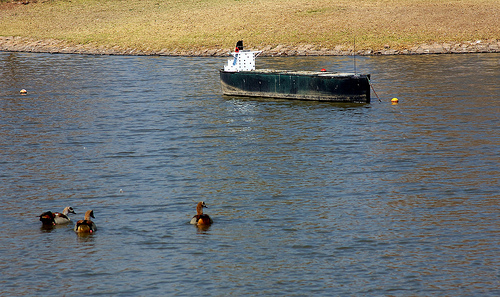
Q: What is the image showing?
A: It is showing a lake.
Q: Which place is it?
A: It is a lake.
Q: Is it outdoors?
A: Yes, it is outdoors.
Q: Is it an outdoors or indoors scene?
A: It is outdoors.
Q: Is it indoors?
A: No, it is outdoors.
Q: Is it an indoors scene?
A: No, it is outdoors.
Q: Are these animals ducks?
A: Yes, all the animals are ducks.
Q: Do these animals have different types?
A: No, all the animals are ducks.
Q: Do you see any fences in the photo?
A: No, there are no fences.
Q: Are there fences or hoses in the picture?
A: No, there are no fences or hoses.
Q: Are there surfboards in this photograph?
A: No, there are no surfboards.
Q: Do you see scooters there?
A: No, there are no scooters.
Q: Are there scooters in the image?
A: No, there are no scooters.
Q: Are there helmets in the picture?
A: No, there are no helmets.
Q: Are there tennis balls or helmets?
A: No, there are no helmets or tennis balls.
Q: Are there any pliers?
A: No, there are no pliers.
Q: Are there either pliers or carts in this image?
A: No, there are no pliers or carts.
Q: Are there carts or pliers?
A: No, there are no pliers or carts.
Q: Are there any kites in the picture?
A: No, there are no kites.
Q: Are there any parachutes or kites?
A: No, there are no kites or parachutes.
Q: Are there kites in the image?
A: No, there are no kites.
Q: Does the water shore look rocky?
A: Yes, the shore is rocky.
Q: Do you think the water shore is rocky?
A: Yes, the shore is rocky.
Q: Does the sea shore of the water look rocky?
A: Yes, the shore is rocky.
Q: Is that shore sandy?
A: No, the shore is rocky.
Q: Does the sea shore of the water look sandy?
A: No, the shore is rocky.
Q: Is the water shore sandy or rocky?
A: The shore is rocky.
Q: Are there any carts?
A: No, there are no carts.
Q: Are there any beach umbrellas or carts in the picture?
A: No, there are no carts or beach umbrellas.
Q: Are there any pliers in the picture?
A: No, there are no pliers.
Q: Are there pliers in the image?
A: No, there are no pliers.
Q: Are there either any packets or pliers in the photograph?
A: No, there are no pliers or packets.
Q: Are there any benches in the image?
A: No, there are no benches.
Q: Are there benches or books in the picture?
A: No, there are no benches or books.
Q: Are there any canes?
A: No, there are no canes.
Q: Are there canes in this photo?
A: No, there are no canes.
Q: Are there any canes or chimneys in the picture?
A: No, there are no canes or chimneys.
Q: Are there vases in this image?
A: No, there are no vases.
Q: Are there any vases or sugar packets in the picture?
A: No, there are no vases or sugar packets.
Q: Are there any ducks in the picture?
A: Yes, there is a duck.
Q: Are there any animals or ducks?
A: Yes, there is a duck.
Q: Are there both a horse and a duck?
A: No, there is a duck but no horses.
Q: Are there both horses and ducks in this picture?
A: No, there is a duck but no horses.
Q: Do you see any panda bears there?
A: No, there are no panda bears.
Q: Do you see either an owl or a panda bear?
A: No, there are no panda bears or owls.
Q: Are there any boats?
A: Yes, there is a boat.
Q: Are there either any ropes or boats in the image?
A: Yes, there is a boat.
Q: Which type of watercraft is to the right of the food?
A: The watercraft is a boat.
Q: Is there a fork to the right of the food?
A: No, there is a boat to the right of the food.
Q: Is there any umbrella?
A: No, there are no umbrellas.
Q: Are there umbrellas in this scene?
A: No, there are no umbrellas.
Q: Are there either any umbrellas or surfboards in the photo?
A: No, there are no umbrellas or surfboards.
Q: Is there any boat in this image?
A: Yes, there is a boat.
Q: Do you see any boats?
A: Yes, there is a boat.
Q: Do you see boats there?
A: Yes, there is a boat.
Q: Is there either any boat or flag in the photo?
A: Yes, there is a boat.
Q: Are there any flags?
A: No, there are no flags.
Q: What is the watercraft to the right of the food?
A: The watercraft is a boat.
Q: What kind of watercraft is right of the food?
A: The watercraft is a boat.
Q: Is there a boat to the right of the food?
A: Yes, there is a boat to the right of the food.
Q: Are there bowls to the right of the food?
A: No, there is a boat to the right of the food.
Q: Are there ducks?
A: Yes, there is a duck.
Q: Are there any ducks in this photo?
A: Yes, there is a duck.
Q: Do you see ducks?
A: Yes, there is a duck.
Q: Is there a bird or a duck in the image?
A: Yes, there is a duck.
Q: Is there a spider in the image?
A: No, there are no spiders.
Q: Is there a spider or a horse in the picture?
A: No, there are no spiders or horses.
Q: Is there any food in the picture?
A: Yes, there is food.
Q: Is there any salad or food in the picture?
A: Yes, there is food.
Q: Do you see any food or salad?
A: Yes, there is food.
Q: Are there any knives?
A: No, there are no knives.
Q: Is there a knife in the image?
A: No, there are no knives.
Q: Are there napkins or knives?
A: No, there are no knives or napkins.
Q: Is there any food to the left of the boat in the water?
A: Yes, there is food to the left of the boat.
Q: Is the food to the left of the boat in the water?
A: Yes, the food is to the left of the boat.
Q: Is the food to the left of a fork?
A: No, the food is to the left of the boat.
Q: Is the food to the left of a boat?
A: Yes, the food is to the left of a boat.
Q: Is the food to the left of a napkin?
A: No, the food is to the left of a boat.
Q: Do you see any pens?
A: No, there are no pens.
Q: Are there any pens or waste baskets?
A: No, there are no pens or waste baskets.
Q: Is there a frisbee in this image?
A: No, there are no frisbees.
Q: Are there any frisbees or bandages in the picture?
A: No, there are no frisbees or bandages.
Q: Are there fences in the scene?
A: No, there are no fences.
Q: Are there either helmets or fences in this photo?
A: No, there are no fences or helmets.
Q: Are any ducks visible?
A: Yes, there are ducks.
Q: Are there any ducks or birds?
A: Yes, there are ducks.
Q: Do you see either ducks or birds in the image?
A: Yes, there are ducks.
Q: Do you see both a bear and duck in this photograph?
A: No, there are ducks but no bears.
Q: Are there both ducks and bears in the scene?
A: No, there are ducks but no bears.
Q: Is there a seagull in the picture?
A: No, there are no seagulls.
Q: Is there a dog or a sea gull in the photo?
A: No, there are no seagulls or dogs.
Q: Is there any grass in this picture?
A: Yes, there is grass.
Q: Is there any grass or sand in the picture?
A: Yes, there is grass.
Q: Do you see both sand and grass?
A: No, there is grass but no sand.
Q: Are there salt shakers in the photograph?
A: No, there are no salt shakers.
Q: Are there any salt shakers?
A: No, there are no salt shakers.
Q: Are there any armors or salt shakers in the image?
A: No, there are no salt shakers or armors.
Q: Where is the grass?
A: The grass is on the beach.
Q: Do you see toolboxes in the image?
A: No, there are no toolboxes.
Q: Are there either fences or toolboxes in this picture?
A: No, there are no toolboxes or fences.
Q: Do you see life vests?
A: No, there are no life vests.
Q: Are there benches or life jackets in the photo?
A: No, there are no life jackets or benches.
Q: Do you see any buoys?
A: Yes, there is a buoy.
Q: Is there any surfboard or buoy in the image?
A: Yes, there is a buoy.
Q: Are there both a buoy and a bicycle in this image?
A: No, there is a buoy but no bicycles.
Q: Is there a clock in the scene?
A: No, there are no clocks.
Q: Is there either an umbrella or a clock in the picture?
A: No, there are no clocks or umbrellas.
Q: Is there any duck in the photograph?
A: Yes, there are ducks.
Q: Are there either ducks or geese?
A: Yes, there are ducks.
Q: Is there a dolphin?
A: No, there are no dolphins.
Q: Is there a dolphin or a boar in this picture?
A: No, there are no dolphins or boars.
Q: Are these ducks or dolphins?
A: These are ducks.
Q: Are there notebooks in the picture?
A: No, there are no notebooks.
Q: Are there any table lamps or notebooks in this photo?
A: No, there are no notebooks or table lamps.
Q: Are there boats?
A: Yes, there is a boat.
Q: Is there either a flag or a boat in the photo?
A: Yes, there is a boat.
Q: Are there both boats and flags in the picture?
A: No, there is a boat but no flags.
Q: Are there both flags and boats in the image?
A: No, there is a boat but no flags.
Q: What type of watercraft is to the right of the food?
A: The watercraft is a boat.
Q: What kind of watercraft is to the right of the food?
A: The watercraft is a boat.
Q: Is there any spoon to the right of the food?
A: No, there is a boat to the right of the food.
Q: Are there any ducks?
A: Yes, there is a duck.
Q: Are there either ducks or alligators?
A: Yes, there is a duck.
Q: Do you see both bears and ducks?
A: No, there is a duck but no bears.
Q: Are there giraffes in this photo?
A: No, there are no giraffes.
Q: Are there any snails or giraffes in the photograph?
A: No, there are no giraffes or snails.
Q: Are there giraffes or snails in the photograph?
A: No, there are no giraffes or snails.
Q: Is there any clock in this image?
A: No, there are no clocks.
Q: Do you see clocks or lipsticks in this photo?
A: No, there are no clocks or lipsticks.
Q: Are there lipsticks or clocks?
A: No, there are no clocks or lipsticks.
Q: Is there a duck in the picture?
A: Yes, there is a duck.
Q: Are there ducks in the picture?
A: Yes, there is a duck.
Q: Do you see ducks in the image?
A: Yes, there is a duck.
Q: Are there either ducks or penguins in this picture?
A: Yes, there is a duck.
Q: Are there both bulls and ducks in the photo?
A: No, there is a duck but no bulls.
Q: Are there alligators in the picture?
A: No, there are no alligators.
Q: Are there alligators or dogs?
A: No, there are no alligators or dogs.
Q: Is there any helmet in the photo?
A: No, there are no helmets.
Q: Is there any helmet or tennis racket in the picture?
A: No, there are no helmets or rackets.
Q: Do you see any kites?
A: No, there are no kites.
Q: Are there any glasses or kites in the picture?
A: No, there are no kites or glasses.